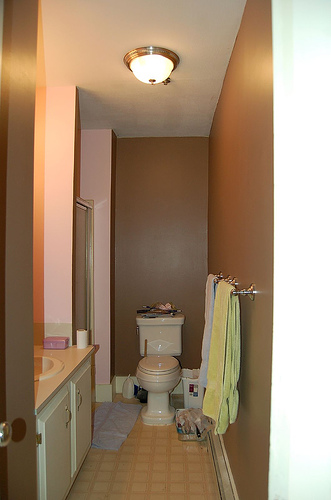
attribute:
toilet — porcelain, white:
[137, 323, 179, 427]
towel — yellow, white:
[211, 296, 241, 417]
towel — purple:
[103, 411, 124, 453]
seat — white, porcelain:
[141, 367, 179, 378]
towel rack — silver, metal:
[241, 287, 259, 298]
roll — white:
[77, 333, 88, 347]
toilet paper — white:
[81, 344, 89, 349]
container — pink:
[44, 339, 72, 351]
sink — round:
[36, 360, 54, 375]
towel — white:
[206, 285, 210, 318]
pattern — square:
[112, 466, 128, 482]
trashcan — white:
[184, 378, 203, 406]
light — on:
[135, 55, 170, 84]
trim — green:
[39, 327, 61, 332]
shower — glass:
[80, 212, 92, 329]